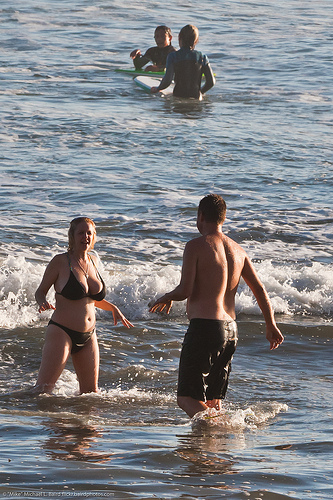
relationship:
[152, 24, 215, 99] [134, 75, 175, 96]
boy on surfboard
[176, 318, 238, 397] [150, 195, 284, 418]
swim trunks on man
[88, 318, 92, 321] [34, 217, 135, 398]
belly button on woman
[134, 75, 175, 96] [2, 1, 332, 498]
surfboard in water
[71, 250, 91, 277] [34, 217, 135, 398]
necklace on woman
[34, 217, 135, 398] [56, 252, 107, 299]
woman wearing bikini top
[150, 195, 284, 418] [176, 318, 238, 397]
man wearing swim trunks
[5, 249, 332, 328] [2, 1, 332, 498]
wave in water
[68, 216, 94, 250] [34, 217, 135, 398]
hair on woman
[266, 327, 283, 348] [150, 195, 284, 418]
hand on man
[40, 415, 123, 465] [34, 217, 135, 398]
reflection of woman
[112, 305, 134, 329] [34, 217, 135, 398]
hand on woman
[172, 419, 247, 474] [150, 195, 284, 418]
reflection of man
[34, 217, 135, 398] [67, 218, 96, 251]
woman has head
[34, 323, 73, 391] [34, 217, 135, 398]
leg on woman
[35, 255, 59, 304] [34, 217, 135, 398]
arm on woman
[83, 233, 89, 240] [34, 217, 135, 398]
nose on woman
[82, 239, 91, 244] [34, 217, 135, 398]
mouth on woman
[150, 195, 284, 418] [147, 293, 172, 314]
man has hand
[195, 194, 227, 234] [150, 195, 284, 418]
head on man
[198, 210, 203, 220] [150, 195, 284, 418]
ear on man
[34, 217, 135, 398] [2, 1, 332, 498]
woman in water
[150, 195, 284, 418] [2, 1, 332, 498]
man in water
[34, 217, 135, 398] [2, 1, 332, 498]
woman enjoying water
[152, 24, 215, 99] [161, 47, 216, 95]
boy in wet suit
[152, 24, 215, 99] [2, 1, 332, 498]
boy in water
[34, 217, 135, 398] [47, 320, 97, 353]
woman in bikini bottom